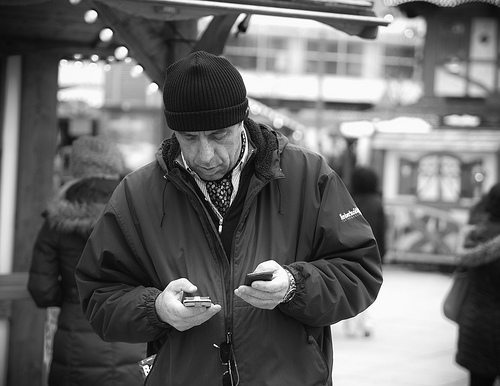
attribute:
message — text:
[5, 35, 474, 365]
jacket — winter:
[27, 127, 148, 373]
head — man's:
[159, 91, 246, 186]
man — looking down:
[67, 50, 386, 384]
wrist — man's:
[281, 264, 301, 308]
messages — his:
[180, 268, 272, 306]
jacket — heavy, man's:
[77, 118, 383, 383]